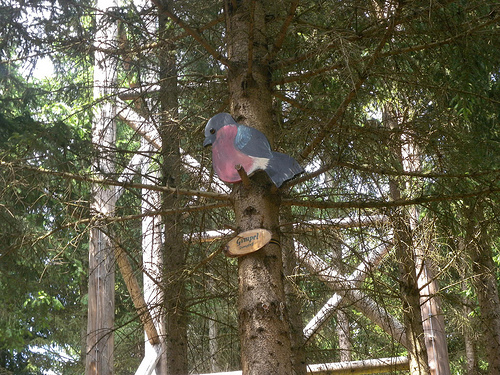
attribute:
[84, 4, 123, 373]
beam — tall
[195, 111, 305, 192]
bird — red, black, white, painted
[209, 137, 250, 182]
chest — red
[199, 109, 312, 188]
bird — blue, pink, white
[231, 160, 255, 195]
branch — brown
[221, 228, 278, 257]
sign — tan, green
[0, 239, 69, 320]
leaves — green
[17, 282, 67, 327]
leaves — green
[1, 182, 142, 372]
tree — brown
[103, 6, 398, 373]
tree — brown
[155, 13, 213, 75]
leaves — green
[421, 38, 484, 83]
leaves — green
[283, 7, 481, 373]
tree — brown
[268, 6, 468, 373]
tree — brown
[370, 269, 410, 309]
leaves — green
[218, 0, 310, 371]
tree — brown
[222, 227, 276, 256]
sign — tan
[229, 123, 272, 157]
wing — blue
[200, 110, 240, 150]
head — blue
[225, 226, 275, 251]
sign — wooden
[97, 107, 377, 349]
scaffold — wooden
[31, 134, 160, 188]
branches — pine, tree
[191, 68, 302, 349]
tree — pine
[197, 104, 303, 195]
bird — wooden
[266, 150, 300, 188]
tail — blue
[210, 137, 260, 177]
belly — red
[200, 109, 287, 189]
bird — wooden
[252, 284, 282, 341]
bark — pine, tree, rough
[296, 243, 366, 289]
logs — wooden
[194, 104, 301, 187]
bird — white, black, red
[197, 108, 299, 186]
bird — red, black, white, wooden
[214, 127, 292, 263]
trunk — tree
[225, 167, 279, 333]
trunk — tree, pine, large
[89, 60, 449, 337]
framework — large, wooden, background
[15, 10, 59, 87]
sky — patch, sunny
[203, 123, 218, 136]
eye — bird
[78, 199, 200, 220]
branch — dead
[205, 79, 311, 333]
tree — pine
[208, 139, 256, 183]
belly — painted, bird's, red